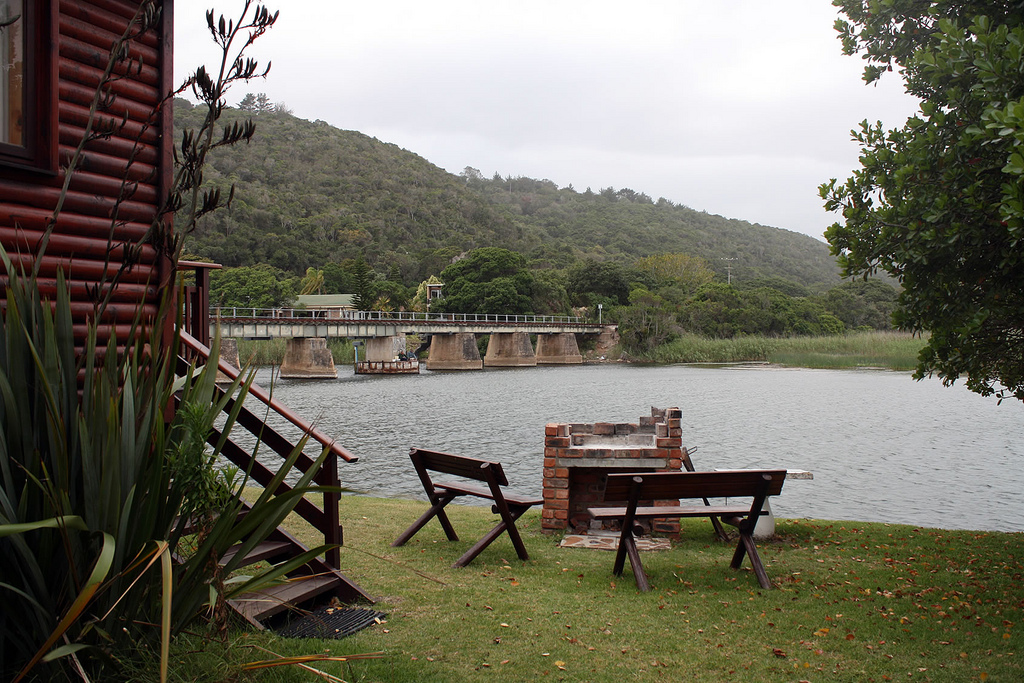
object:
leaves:
[542, 651, 550, 655]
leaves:
[813, 628, 830, 637]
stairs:
[172, 322, 393, 642]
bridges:
[280, 337, 338, 379]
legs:
[452, 505, 531, 569]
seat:
[586, 506, 769, 521]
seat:
[432, 482, 545, 506]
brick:
[540, 406, 685, 550]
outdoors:
[0, 0, 1024, 683]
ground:
[0, 487, 1024, 683]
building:
[0, 0, 395, 644]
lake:
[203, 359, 1024, 533]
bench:
[588, 470, 790, 593]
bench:
[392, 446, 543, 567]